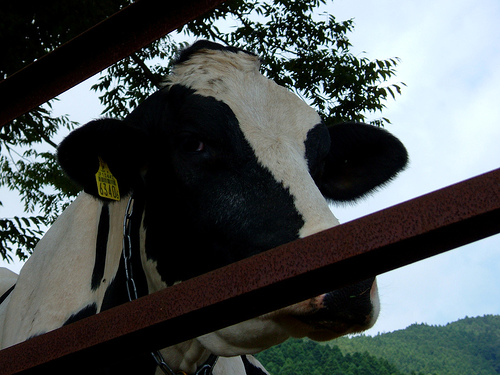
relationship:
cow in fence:
[0, 39, 416, 372] [2, 2, 499, 374]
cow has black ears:
[0, 39, 416, 372] [43, 97, 415, 206]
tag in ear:
[96, 160, 121, 202] [47, 104, 134, 200]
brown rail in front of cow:
[190, 167, 429, 316] [35, 35, 438, 306]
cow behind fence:
[0, 39, 410, 375] [18, 161, 481, 341]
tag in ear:
[96, 160, 121, 202] [58, 114, 133, 201]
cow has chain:
[0, 39, 416, 372] [119, 181, 216, 372]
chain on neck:
[114, 192, 189, 365] [95, 176, 193, 364]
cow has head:
[0, 39, 410, 375] [156, 80, 336, 321]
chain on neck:
[120, 192, 220, 375] [92, 155, 240, 373]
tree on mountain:
[347, 306, 497, 370] [370, 308, 494, 373]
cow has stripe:
[0, 39, 416, 372] [195, 51, 342, 232]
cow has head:
[0, 39, 416, 372] [54, 36, 408, 353]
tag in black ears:
[96, 160, 121, 202] [54, 116, 147, 206]